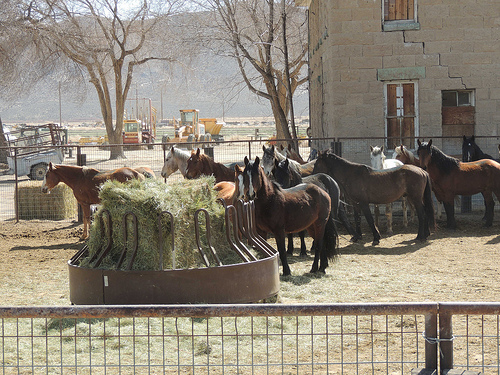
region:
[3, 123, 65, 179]
A short horse trailer.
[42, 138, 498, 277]
Herd of horses in a pen.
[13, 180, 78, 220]
A bale of hay.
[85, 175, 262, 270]
Hay in a bale feeder.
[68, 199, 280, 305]
A bale feeder for horses.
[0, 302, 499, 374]
Metal fence to keep horses in.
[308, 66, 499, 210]
Building made of stone blocks.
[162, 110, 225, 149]
Yellow grader sits on a road.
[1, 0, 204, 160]
Tree without leaves.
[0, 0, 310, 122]
Mountains near a farm.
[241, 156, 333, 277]
a dark brown horse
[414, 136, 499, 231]
a dark brown horse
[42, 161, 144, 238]
a dark brown horse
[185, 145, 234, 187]
a dark brown horse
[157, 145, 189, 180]
a white horse head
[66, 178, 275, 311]
a horse hay feeder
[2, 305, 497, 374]
a metal wire fence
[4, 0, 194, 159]
a large bare tree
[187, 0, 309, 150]
a large bare tree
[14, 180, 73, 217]
a barrel of hay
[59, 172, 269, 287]
hay in a cement and metal container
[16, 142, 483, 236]
group of horses in an enclosed area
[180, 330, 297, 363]
ground covered with hay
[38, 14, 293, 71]
trees with no leaves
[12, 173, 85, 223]
square bail of hay outside of fence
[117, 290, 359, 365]
metal fence to hold horses in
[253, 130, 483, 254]
brown and white horses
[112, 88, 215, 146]
farm equipment in the near distance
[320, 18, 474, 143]
tan brick building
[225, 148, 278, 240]
horses eating hay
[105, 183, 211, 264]
hay in the feeder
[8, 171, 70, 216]
bale of hay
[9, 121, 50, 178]
trailer on the other side of the fence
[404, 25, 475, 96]
crack in the building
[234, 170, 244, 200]
horse has white strip on it's face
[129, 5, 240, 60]
tree does not have leaves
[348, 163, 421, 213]
horse is dark brown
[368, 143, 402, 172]
horse is white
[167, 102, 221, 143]
equipment is yellow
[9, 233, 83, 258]
shadow of the horse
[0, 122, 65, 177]
Back of white pickup truck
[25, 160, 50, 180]
Left rear wheel of white truck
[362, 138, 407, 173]
White horse in herd of horses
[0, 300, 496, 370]
Wire fence with bar across the top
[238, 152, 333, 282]
Dark brown horse in corral of horses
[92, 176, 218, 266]
Batch of hay for horses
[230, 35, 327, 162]
Tall tree in front of building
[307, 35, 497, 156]
White building in back of horses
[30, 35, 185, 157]
Tall tree in middle of grounds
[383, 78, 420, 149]
Wood door in white building